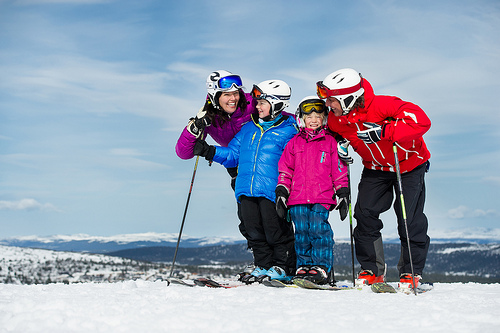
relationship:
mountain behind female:
[140, 239, 494, 268] [176, 68, 254, 253]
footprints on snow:
[3, 288, 488, 330] [2, 277, 498, 332]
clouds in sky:
[3, 0, 498, 225] [3, 2, 497, 244]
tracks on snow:
[75, 284, 485, 331] [16, 237, 111, 279]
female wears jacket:
[176, 68, 254, 253] [167, 107, 248, 167]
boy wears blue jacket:
[193, 79, 300, 282] [214, 111, 306, 198]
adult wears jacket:
[317, 67, 432, 288] [329, 80, 431, 172]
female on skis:
[176, 68, 254, 253] [368, 273, 395, 295]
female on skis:
[176, 68, 254, 253] [408, 276, 435, 299]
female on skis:
[176, 68, 254, 253] [289, 276, 346, 291]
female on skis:
[176, 68, 254, 253] [254, 272, 288, 287]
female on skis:
[176, 68, 254, 253] [196, 272, 242, 289]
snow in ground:
[0, 283, 500, 330] [2, 281, 499, 331]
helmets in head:
[203, 67, 365, 131] [316, 67, 364, 112]